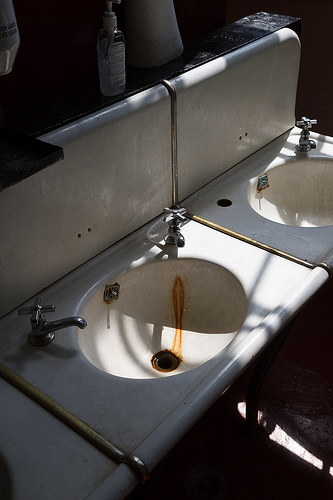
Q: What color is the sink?
A: White.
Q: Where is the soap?
A: On the sink wall.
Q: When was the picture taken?
A: Daytime.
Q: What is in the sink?
A: Rust.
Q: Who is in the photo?
A: Nobody.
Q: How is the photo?
A: Clear.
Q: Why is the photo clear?
A: Its during the day.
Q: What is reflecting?
A: The sun.